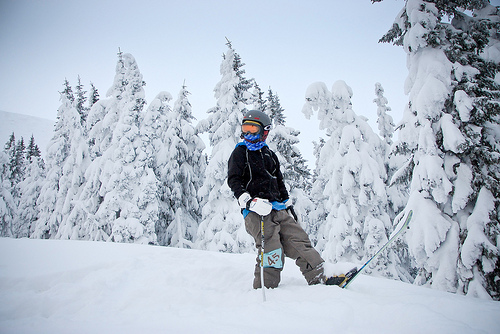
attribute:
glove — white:
[244, 196, 279, 218]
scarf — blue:
[235, 134, 274, 152]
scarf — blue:
[232, 128, 278, 154]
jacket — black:
[225, 142, 300, 204]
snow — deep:
[0, 236, 499, 330]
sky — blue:
[4, 1, 423, 156]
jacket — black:
[226, 140, 289, 210]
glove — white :
[238, 185, 281, 223]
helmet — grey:
[241, 108, 270, 143]